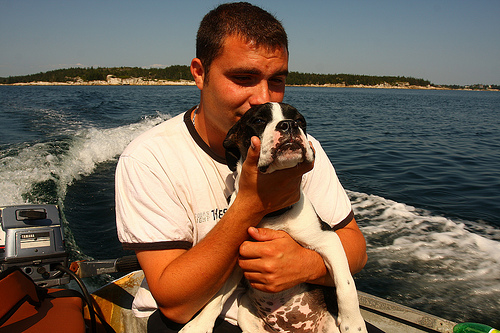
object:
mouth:
[234, 111, 246, 120]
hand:
[237, 222, 318, 293]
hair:
[193, 2, 290, 84]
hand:
[240, 136, 315, 217]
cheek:
[211, 77, 253, 116]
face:
[207, 23, 290, 138]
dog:
[180, 103, 350, 330]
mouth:
[259, 136, 316, 174]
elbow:
[147, 261, 215, 324]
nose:
[249, 82, 273, 104]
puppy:
[173, 102, 368, 333]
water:
[0, 85, 500, 332]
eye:
[289, 111, 298, 119]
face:
[221, 101, 316, 172]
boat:
[0, 201, 500, 333]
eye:
[221, 64, 260, 87]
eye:
[268, 73, 288, 86]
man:
[112, 3, 366, 333]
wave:
[0, 106, 177, 265]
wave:
[340, 157, 495, 307]